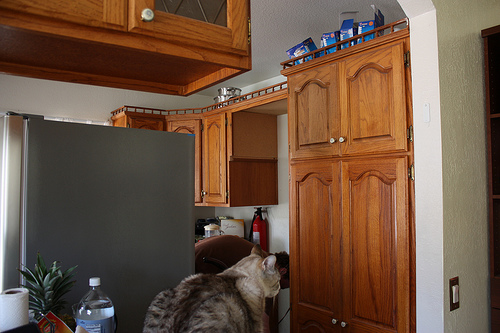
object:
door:
[286, 63, 340, 160]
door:
[340, 41, 405, 153]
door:
[288, 157, 339, 332]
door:
[337, 155, 409, 330]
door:
[200, 111, 229, 205]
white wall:
[439, 103, 490, 268]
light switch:
[414, 100, 431, 125]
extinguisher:
[248, 203, 269, 254]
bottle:
[72, 276, 117, 332]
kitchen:
[1, 4, 405, 329]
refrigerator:
[2, 111, 200, 330]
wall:
[394, 29, 499, 331]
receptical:
[443, 276, 464, 314]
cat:
[140, 245, 283, 331]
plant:
[21, 258, 82, 324]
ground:
[413, 135, 445, 206]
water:
[79, 302, 114, 321]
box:
[355, 6, 385, 43]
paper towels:
[0, 285, 30, 330]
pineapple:
[15, 255, 77, 329]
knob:
[140, 7, 155, 19]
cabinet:
[110, 18, 415, 331]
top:
[280, 18, 408, 75]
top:
[111, 81, 287, 116]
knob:
[333, 136, 353, 144]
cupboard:
[0, 2, 249, 95]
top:
[85, 275, 103, 288]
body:
[141, 267, 257, 331]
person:
[194, 235, 289, 288]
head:
[238, 244, 280, 300]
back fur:
[147, 273, 239, 330]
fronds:
[17, 255, 82, 324]